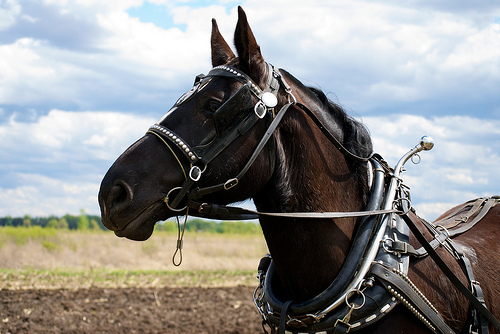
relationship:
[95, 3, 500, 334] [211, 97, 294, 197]
horse wearing straps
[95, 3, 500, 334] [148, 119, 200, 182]
horse wearing straps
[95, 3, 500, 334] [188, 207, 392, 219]
horse wearing straps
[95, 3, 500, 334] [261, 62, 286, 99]
horse wearing straps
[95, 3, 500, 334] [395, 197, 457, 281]
horse wearing straps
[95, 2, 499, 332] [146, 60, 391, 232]
horse wearing straps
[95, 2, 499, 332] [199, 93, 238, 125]
horse has eye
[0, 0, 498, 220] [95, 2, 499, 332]
sky above horse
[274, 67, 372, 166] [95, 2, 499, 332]
mane of horse